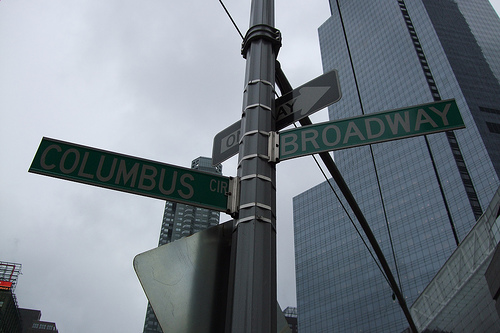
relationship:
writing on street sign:
[40, 144, 228, 201] [28, 136, 231, 215]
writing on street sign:
[281, 102, 452, 157] [277, 98, 464, 161]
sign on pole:
[235, 78, 275, 169] [226, 1, 284, 332]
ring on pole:
[242, 103, 272, 119] [226, 1, 284, 332]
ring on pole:
[238, 130, 270, 145] [226, 1, 284, 332]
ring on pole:
[238, 153, 270, 170] [226, 1, 284, 332]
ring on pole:
[241, 172, 275, 188] [226, 1, 284, 332]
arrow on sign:
[295, 86, 331, 115] [212, 70, 342, 168]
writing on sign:
[226, 98, 297, 148] [212, 70, 342, 168]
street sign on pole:
[28, 136, 231, 215] [226, 1, 284, 332]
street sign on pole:
[277, 98, 464, 161] [226, 1, 284, 332]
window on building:
[308, 214, 314, 221] [293, 1, 499, 333]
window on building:
[393, 171, 400, 181] [293, 1, 499, 333]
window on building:
[409, 150, 417, 159] [293, 1, 499, 333]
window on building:
[418, 202, 426, 211] [293, 1, 499, 333]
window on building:
[357, 175, 365, 182] [293, 1, 499, 333]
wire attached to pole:
[219, 1, 396, 293] [226, 1, 284, 332]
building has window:
[293, 1, 499, 333] [308, 214, 314, 221]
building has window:
[293, 1, 499, 333] [357, 175, 365, 182]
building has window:
[293, 1, 499, 333] [393, 171, 400, 181]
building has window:
[293, 1, 499, 333] [418, 202, 426, 211]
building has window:
[293, 1, 499, 333] [409, 150, 417, 159]